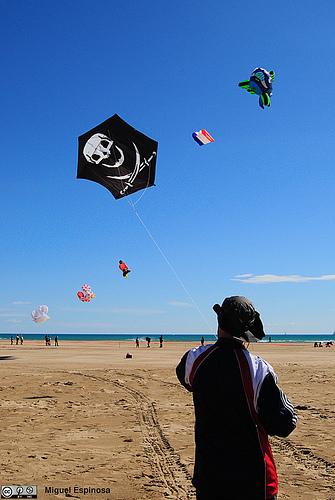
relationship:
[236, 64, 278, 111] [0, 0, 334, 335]
kite in sky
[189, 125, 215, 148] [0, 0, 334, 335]
kite in sky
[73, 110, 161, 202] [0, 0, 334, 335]
kite in sky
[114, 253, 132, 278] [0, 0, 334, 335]
kite in sky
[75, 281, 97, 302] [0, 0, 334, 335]
kite in sky